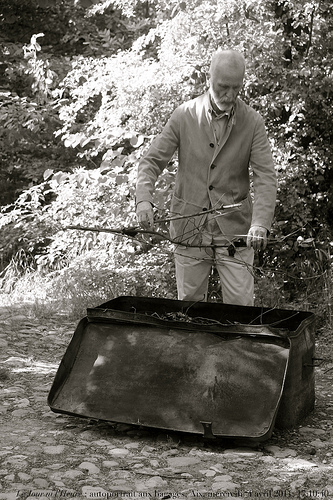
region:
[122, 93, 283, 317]
the man is wearing a blazer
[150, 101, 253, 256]
the man is wearing a blazer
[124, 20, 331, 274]
the man is wearing a blazer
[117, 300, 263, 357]
branches in metal box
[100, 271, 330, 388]
branches in metal box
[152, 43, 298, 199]
old man has gray hair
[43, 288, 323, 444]
black box with sticks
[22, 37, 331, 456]
man puts sticks in a black box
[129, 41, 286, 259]
man wears a jacket with buttons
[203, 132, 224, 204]
buttons in a jacket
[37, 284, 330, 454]
box is open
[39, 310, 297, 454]
lid of box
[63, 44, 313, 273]
man holds sticks with both hands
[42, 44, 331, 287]
man is breaking sticks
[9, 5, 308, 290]
trees back of man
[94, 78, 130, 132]
sunlight hitting the leaves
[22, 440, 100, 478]
stones on the ground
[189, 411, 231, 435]
lock on the suitcase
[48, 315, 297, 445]
large cover on the suitcase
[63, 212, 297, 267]
large twig in man's hand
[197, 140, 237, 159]
black button on jacket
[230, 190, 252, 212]
side pocket in jacket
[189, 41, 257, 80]
man's bald head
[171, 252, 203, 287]
wrinkles in tan pants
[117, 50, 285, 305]
man standing on the ground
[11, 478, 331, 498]
Name of Photographer and Brand Name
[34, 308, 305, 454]
Rectangle Lid Leaning On Side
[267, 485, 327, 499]
Year and Time Of Photograph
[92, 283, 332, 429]
Box Made of Heavy Material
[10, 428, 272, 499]
Stones Gravel and Grass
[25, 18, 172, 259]
Light beams on Fauna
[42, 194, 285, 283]
Broken Twigs and Sticks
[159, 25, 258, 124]
Balding Elderly Man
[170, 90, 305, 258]
Buttoned Down Sweater Partially Buttoned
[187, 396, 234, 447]
Metal Latch Unlatched and Sticking Up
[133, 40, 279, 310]
a man wearing a button up jacket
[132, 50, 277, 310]
a person holding sticks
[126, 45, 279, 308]
a person with balding hair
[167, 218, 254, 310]
a pair of kaki pants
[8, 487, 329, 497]
tiny words at the bottom of the picture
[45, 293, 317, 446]
a large brownish case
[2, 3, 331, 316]
some bushes behind the man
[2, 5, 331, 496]
a black and white photograph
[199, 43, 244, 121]
a man looking downwards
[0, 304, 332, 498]
a cobblestone road